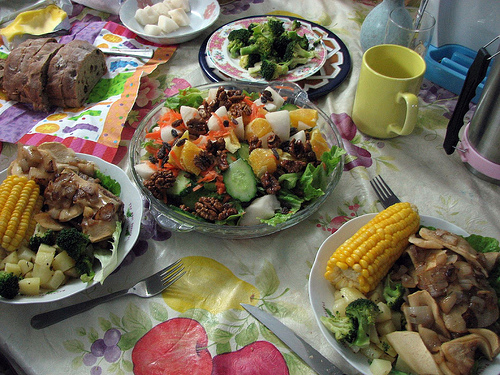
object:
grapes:
[87, 362, 105, 375]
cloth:
[0, 0, 499, 375]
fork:
[27, 257, 186, 332]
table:
[0, 0, 499, 375]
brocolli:
[345, 298, 385, 350]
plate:
[126, 78, 344, 239]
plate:
[196, 14, 351, 100]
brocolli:
[259, 59, 286, 79]